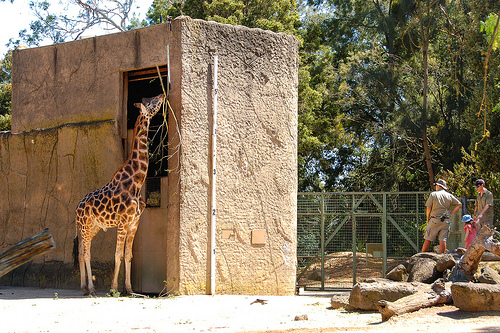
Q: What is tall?
A: Giraffe.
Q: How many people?
A: Three.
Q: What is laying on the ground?
A: The logs.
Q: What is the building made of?
A: Some bricks.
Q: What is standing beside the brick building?
A: A giraffe.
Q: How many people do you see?
A: Only three.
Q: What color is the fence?
A: A green.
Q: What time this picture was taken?
A: In daytime.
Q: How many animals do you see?
A: Only one.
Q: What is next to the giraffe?
A: A building.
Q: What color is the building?
A: Tan.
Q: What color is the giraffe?
A: Brown and white.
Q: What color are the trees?
A: Green.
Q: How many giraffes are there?
A: One.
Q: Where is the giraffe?
A: Next to the building.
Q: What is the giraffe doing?
A: Eating.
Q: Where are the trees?
A: Behind the fence.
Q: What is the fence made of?
A: Metal.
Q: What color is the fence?
A: Black and green.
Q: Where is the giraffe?
A: Shade.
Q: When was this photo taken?
A: Daytime.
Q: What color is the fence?
A: Light green.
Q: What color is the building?
A: Tan.